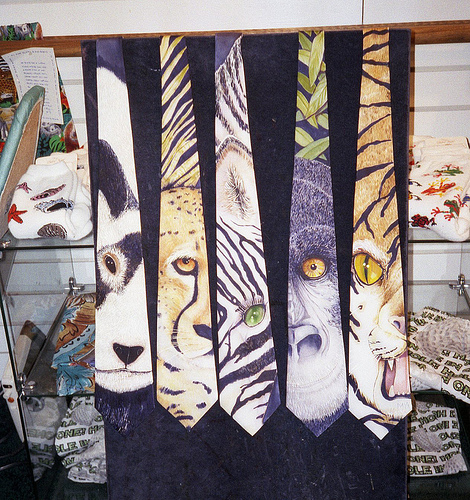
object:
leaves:
[307, 30, 326, 89]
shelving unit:
[0, 233, 108, 500]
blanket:
[6, 145, 93, 242]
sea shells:
[29, 182, 67, 201]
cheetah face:
[154, 185, 219, 436]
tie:
[214, 33, 283, 438]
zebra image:
[212, 34, 282, 439]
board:
[78, 27, 418, 500]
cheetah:
[156, 32, 218, 433]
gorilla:
[284, 24, 351, 439]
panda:
[94, 35, 155, 396]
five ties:
[93, 23, 414, 443]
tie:
[93, 32, 155, 397]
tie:
[156, 34, 220, 434]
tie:
[345, 27, 412, 443]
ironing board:
[0, 82, 47, 249]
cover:
[0, 84, 47, 200]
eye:
[170, 257, 198, 276]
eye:
[95, 244, 128, 294]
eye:
[242, 303, 267, 328]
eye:
[299, 255, 329, 281]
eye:
[352, 252, 386, 286]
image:
[346, 22, 415, 442]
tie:
[284, 27, 351, 438]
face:
[285, 155, 349, 439]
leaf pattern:
[293, 28, 330, 162]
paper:
[1, 45, 65, 124]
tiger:
[345, 26, 415, 442]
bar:
[0, 19, 469, 58]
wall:
[0, 0, 470, 500]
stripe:
[165, 140, 199, 184]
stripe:
[160, 86, 194, 134]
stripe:
[161, 46, 189, 97]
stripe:
[160, 34, 187, 78]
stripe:
[178, 169, 201, 188]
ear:
[215, 134, 265, 258]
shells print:
[32, 194, 76, 213]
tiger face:
[348, 221, 415, 433]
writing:
[18, 59, 52, 114]